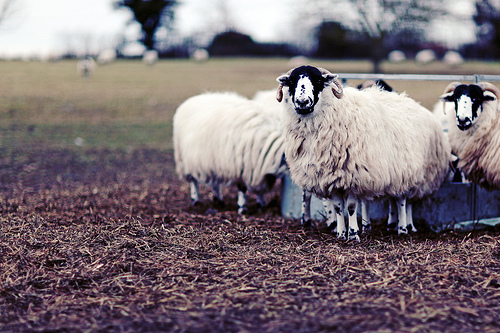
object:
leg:
[397, 199, 407, 237]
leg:
[346, 195, 360, 242]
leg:
[332, 192, 343, 239]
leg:
[301, 188, 312, 225]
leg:
[387, 197, 397, 235]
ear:
[275, 75, 288, 103]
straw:
[3, 257, 156, 332]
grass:
[3, 121, 172, 150]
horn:
[276, 84, 284, 103]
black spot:
[350, 205, 355, 213]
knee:
[347, 202, 356, 216]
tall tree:
[116, 3, 174, 66]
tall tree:
[347, 0, 433, 70]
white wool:
[340, 103, 440, 189]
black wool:
[300, 66, 314, 73]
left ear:
[322, 74, 339, 88]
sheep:
[171, 91, 288, 215]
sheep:
[432, 81, 500, 191]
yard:
[0, 43, 498, 331]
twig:
[0, 198, 498, 331]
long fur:
[309, 131, 401, 179]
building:
[216, 32, 271, 60]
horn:
[323, 70, 344, 99]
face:
[454, 84, 484, 131]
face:
[288, 65, 324, 114]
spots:
[332, 204, 344, 217]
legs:
[406, 202, 417, 233]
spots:
[298, 84, 308, 98]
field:
[0, 60, 500, 333]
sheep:
[274, 65, 446, 244]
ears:
[320, 68, 343, 99]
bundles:
[392, 45, 435, 63]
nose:
[296, 99, 310, 107]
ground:
[119, 230, 396, 312]